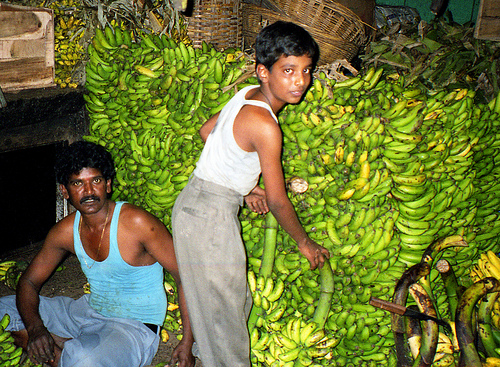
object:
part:
[199, 293, 237, 315]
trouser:
[168, 171, 254, 367]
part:
[327, 302, 348, 322]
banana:
[335, 310, 350, 329]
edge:
[243, 283, 255, 328]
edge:
[120, 254, 136, 270]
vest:
[72, 196, 169, 329]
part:
[159, 345, 175, 353]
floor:
[0, 238, 199, 365]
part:
[100, 332, 121, 350]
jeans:
[0, 292, 164, 367]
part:
[21, 163, 41, 197]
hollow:
[1, 137, 71, 261]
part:
[71, 145, 96, 155]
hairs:
[51, 138, 119, 199]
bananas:
[387, 171, 429, 187]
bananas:
[372, 226, 385, 246]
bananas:
[349, 205, 367, 233]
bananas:
[335, 186, 357, 203]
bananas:
[395, 222, 430, 236]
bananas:
[359, 228, 376, 250]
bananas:
[333, 212, 354, 231]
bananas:
[335, 145, 345, 166]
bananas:
[307, 136, 325, 150]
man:
[0, 137, 197, 364]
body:
[168, 85, 333, 367]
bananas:
[332, 76, 362, 88]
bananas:
[361, 206, 376, 228]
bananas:
[187, 80, 204, 115]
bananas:
[359, 159, 370, 179]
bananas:
[469, 146, 485, 163]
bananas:
[473, 151, 485, 165]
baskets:
[240, 2, 362, 73]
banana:
[281, 310, 337, 355]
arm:
[122, 208, 195, 342]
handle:
[367, 294, 410, 333]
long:
[168, 175, 257, 367]